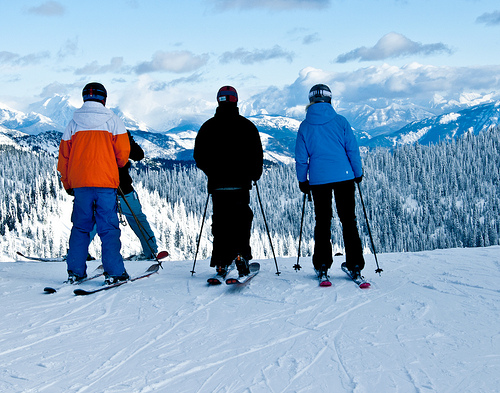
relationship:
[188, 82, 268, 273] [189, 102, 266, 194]
man wearing jacket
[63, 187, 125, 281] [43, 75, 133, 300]
blue pants on man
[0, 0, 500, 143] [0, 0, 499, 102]
cloud are in sky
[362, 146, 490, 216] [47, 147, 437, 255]
trees in valley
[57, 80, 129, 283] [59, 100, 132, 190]
man wearing jacket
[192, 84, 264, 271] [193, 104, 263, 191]
man wearing jacket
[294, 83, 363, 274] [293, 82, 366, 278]
man wearing blue jacket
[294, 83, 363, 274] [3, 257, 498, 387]
man looking over slope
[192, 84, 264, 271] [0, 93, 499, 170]
man looking at mountain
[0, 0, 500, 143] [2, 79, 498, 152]
cloud on horizon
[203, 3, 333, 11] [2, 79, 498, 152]
cloud on horizon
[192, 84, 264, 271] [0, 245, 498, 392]
man in snow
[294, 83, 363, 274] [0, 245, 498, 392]
man in snow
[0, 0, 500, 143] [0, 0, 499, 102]
cloud in sky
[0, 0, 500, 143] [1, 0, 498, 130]
cloud in sky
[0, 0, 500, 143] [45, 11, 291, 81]
cloud in sky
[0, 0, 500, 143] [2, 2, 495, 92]
cloud in sky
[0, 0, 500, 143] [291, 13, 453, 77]
cloud in sky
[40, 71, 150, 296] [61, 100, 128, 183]
man wearing jacket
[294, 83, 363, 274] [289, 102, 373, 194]
man wearing jacket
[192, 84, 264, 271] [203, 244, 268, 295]
man wearing skis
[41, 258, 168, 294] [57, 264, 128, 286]
skis on feet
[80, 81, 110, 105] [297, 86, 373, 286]
helmet on man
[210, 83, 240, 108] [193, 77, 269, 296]
helmet on man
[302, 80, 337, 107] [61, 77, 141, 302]
helmet on man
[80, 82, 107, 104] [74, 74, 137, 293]
helmet on person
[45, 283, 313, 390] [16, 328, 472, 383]
tracks in snow